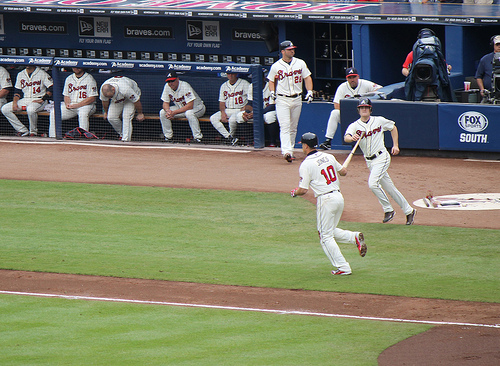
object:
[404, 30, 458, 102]
camera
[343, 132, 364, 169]
baseball bat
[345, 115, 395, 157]
shirt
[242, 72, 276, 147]
baseball players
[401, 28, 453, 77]
cameraman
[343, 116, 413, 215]
uniform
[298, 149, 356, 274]
uniform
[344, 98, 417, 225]
baseball player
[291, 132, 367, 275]
baseball player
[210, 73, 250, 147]
baseball players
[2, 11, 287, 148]
dugout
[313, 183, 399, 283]
pants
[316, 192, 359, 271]
pants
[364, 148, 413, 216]
pants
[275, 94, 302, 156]
pants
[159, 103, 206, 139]
pants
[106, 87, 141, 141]
pants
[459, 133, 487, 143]
south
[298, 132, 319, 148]
baseball helmet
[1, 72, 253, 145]
bench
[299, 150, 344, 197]
shirt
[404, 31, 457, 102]
cloth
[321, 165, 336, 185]
number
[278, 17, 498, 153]
sideline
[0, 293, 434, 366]
grass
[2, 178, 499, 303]
grass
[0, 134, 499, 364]
field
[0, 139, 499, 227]
dirt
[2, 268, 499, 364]
dirt